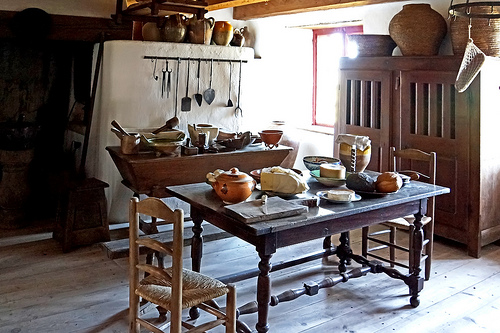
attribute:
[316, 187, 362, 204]
plate — medium sized, cheese plate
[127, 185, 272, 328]
chair — wood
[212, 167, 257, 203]
pottery — orange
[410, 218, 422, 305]
wood leg — wooden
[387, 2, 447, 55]
basket — large, brown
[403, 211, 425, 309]
leg — wooden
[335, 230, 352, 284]
leg — wooden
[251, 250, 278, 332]
leg — wooden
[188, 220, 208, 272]
leg — wooden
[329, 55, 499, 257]
cabinet — wooden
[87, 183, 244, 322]
chair — wooden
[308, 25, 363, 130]
window — red framed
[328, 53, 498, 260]
pantry — large, brown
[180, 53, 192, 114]
spatula — large, steel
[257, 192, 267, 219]
knife — large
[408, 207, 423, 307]
leg — wood